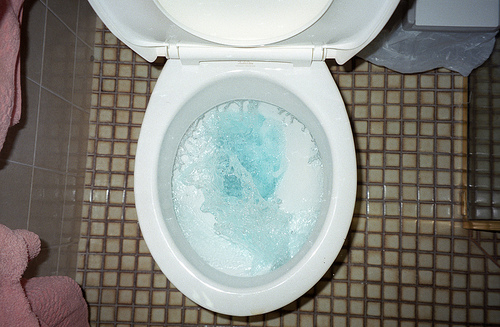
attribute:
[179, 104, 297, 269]
product — blue, here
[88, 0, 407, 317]
toilet — white, present, flushing, clean, here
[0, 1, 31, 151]
towel — pink, here, present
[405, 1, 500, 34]
bin — white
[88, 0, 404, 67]
seat — up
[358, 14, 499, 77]
bag — white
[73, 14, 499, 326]
floor — dirty, here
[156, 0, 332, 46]
lid — toilet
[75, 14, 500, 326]
tiles — gross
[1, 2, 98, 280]
wall — brown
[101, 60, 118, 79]
tile — small, here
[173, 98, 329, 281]
water — blue, moving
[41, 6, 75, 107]
tile — large